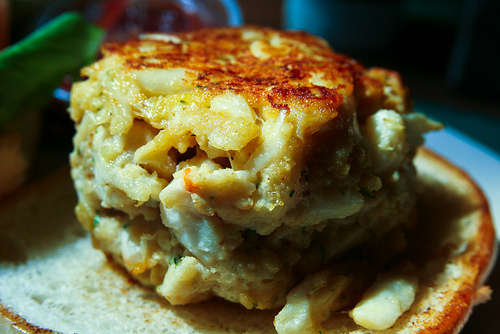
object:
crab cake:
[64, 21, 446, 333]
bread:
[0, 144, 495, 333]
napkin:
[0, 8, 105, 128]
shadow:
[302, 159, 410, 273]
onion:
[348, 257, 420, 329]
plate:
[2, 109, 499, 332]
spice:
[180, 98, 186, 104]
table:
[405, 98, 499, 334]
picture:
[1, 1, 500, 333]